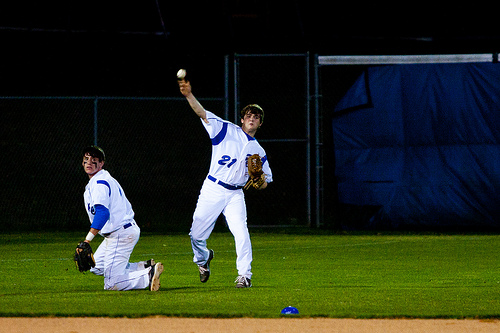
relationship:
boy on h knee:
[73, 144, 165, 293] [102, 271, 119, 290]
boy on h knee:
[73, 144, 165, 293] [86, 260, 101, 274]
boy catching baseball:
[174, 79, 272, 290] [175, 67, 184, 77]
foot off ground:
[195, 242, 215, 284] [2, 230, 498, 318]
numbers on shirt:
[218, 155, 240, 167] [202, 109, 272, 189]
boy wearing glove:
[73, 144, 166, 296] [73, 240, 95, 277]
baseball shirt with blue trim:
[77, 172, 143, 237] [96, 174, 113, 196]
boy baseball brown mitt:
[174, 79, 272, 290] [239, 151, 265, 188]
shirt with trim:
[202, 109, 272, 189] [208, 117, 229, 149]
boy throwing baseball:
[174, 79, 272, 290] [175, 65, 186, 79]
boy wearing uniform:
[167, 75, 277, 295] [185, 112, 270, 264]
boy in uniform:
[174, 79, 272, 290] [189, 120, 275, 279]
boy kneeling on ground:
[73, 144, 165, 293] [0, 215, 498, 331]